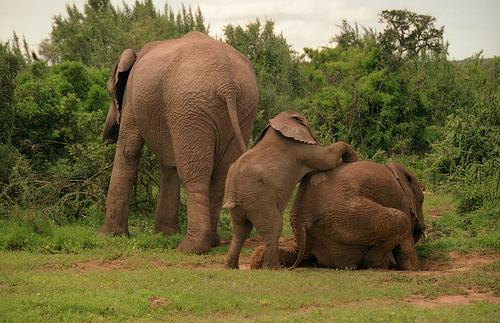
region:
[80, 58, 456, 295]
family of elephants in the wild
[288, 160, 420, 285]
an elephant kneeling on the ground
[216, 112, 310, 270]
a baby elephant climbing on his mother's back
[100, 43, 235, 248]
an elephant looking for food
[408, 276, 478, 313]
dirt patches in the grass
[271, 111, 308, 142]
a flappy gray ear on a head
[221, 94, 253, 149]
a long gray tail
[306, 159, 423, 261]
elephant digging a hole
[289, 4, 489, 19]
an overcast gray sky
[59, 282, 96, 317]
green grass growing in a clearing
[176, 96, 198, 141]
gray wrinkled skin on hind quarters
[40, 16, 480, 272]
elephants playing in the forest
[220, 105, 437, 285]
a baby elephant is on top of his mom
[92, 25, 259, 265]
an elephant standing around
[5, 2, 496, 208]
trees and bushes are in the background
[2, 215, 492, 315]
grass and red clay are in the clearing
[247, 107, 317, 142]
the baby elephant's ears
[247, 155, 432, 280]
an elephant rolling around in the mud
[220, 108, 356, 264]
the baby elephant is standing on his hind legs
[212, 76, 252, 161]
the matriarch's brown tail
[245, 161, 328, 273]
the elephant is on one knee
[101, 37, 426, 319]
Three elephants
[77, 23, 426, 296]
Elephants in the wild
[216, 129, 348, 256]
Baby elephant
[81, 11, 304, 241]
Large mother elephant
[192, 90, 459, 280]
Little elephant playing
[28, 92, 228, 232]
Brush and trees behind the elephants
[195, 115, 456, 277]
Elephants playing in the mud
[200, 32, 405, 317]
Elephant on the other one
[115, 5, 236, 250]
Elephant walking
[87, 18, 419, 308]
A herd of elephants in the wild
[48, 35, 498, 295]
three elephants in grass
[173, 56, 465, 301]
two elephants playing together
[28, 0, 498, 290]
elephants in front of trees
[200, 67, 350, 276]
small elephant wagging its tail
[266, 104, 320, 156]
elephant ear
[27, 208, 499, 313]
dirt patches in the grass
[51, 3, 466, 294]
elephants playing together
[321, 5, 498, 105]
trees in front of gray skies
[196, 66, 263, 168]
elephant tail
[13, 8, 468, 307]
Mama and baby elephants